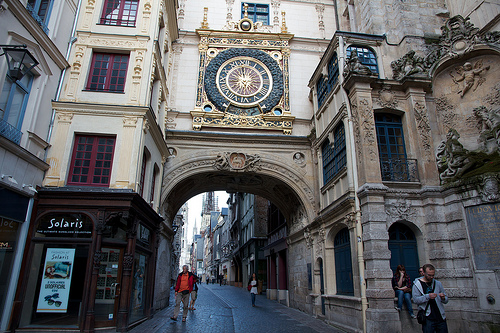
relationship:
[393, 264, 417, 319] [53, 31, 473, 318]
person leaning against building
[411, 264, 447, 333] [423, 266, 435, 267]
man has hair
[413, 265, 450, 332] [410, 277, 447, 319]
man wearing hoodie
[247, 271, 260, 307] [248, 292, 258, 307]
person wearing jeans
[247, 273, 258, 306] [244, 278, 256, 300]
person wearing shirt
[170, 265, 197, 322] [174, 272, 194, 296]
man wearing shirt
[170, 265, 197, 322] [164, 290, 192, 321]
man wearing pants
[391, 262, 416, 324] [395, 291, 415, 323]
person wearing blue jeans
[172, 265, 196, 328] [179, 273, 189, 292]
man in shirt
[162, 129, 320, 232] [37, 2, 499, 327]
archway on a building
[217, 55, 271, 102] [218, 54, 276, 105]
numerals on clock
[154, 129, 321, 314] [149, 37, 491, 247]
archway under building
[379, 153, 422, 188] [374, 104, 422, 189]
iron gate at window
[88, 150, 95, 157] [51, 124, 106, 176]
framing at window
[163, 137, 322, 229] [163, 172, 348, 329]
arch with a walkway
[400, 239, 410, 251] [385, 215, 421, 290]
part of a door